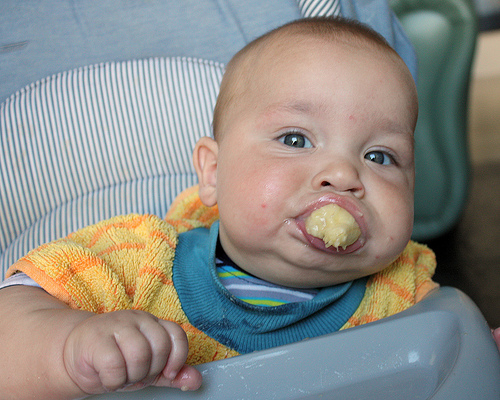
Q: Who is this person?
A: Baby.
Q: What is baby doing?
A: Eating.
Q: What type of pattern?
A: Stripes.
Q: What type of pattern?
A: Stripes.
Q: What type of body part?
A: Hand.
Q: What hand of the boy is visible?
A: Right.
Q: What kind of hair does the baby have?
A: Short and brown.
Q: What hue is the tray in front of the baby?
A: Light blue.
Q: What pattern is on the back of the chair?
A: Blue and white stripes.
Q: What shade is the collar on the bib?
A: Blue.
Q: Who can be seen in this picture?
A: A baby.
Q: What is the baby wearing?
A: Orange and blue bib.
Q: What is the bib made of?
A: Terry cloth.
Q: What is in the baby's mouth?
A: Banana.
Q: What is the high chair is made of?
A: Plastic.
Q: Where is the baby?
A: High chair.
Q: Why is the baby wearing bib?
A: To protect the clothing from stain.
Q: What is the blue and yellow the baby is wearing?
A: Bib.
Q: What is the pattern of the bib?
A: Striped.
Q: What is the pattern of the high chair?
A: Stripped.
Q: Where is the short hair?
A: Head.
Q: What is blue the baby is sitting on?
A: High chair.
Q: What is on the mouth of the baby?
A: Banana.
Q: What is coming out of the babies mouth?
A: Food.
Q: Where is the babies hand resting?
A: On a tray.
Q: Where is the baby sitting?
A: A highchair.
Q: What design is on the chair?
A: Stripes.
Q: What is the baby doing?
A: Eating.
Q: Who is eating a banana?
A: Baby.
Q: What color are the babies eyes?
A: Blue.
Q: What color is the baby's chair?
A: Blue.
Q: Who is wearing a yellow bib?
A: Baby.